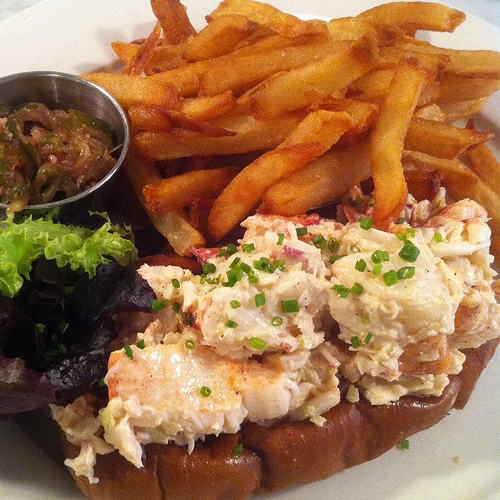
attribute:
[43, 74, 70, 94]
container — silver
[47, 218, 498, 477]
onions — green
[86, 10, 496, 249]
fries — french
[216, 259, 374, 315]
toppings — pile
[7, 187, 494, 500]
food — big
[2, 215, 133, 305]
vegetable — green, leafy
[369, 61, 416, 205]
fry — orange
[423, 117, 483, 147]
fry — orange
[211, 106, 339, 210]
fry — orange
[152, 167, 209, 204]
fry — orange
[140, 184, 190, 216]
fry — orange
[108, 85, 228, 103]
fry — orange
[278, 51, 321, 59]
fry — orange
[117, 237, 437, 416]
tuna — pink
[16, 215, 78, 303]
lettuce —  green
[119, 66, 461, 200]
fries — golden, french